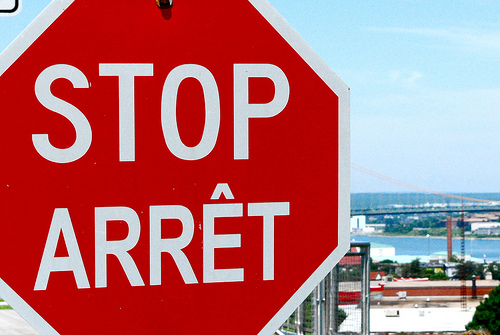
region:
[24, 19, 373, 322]
Large red street sign.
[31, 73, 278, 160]
White lettering on sign.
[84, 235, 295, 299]
White lettering on sign.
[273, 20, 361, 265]
White edging on red sign.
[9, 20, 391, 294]
Sign has 8 sides.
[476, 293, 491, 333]
Green leaves on tree top.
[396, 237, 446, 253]
Blue water in distance.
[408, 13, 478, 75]
White wispy clouds in sky.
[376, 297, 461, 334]
Light colored roof to building.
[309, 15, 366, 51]
Sky is blue in color.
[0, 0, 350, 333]
Large, red stop sign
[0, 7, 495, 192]
Clear blue sky with cloud sprinkes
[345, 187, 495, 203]
Long gentle cascading hills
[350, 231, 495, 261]
Wide area of water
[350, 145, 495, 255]
Long, high up suspesion bridge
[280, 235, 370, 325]
Tall concrete construction columns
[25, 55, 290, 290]
Large writings in white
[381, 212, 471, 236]
Green vegetation among buildings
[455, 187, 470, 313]
Tall thin metallic structure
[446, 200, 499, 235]
Group of buildings in the background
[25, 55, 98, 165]
The S on the stop sign.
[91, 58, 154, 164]
The T in the word Stop on the stop sign.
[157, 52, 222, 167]
The O on the stop sign.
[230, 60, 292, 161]
The P on the stop sign.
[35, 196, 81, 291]
The A on the stop sign.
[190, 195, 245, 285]
The E on the stop sign.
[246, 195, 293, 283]
The T in the word Arret on the stop sign.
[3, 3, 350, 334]
The stop sign on the left.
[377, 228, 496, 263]
The water in the background.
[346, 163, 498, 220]
The bridge in the background.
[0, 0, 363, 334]
sign on front the ocean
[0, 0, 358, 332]
a STOP sign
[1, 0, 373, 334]
STOP sign is red and white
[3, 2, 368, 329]
letters of STOP sign are white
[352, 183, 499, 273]
blue water of the ocean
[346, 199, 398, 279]
a building in front the ocean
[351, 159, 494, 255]
a bridge over the water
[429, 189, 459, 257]
a red pole of bridge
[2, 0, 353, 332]
border of STOP sign is white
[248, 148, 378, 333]
metal structure behind a STOP sign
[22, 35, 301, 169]
white writing on the sign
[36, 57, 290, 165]
the word "stop" on sign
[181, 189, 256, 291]
the letter E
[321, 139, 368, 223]
white border of the sign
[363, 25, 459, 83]
blue sky in the background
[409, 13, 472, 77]
white clouds in the sky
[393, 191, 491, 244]
land in the background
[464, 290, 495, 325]
green leaves on the tree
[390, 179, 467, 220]
bridge in the background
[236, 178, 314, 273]
the letter T